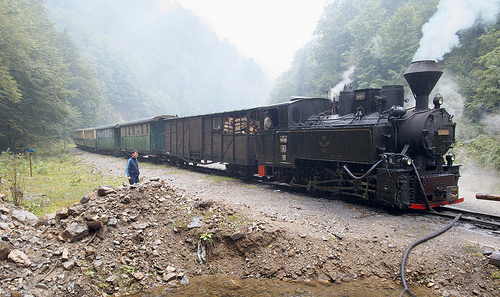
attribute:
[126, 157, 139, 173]
jacket — blue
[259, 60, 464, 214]
engine — old fashioned, historic, polluting, moving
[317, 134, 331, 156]
logo — gold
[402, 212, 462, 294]
hose — black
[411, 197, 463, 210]
bumper — red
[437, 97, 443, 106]
light — mounted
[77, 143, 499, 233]
tracks — black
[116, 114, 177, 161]
car — green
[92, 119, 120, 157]
car — green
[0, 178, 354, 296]
dirt — piled, tall